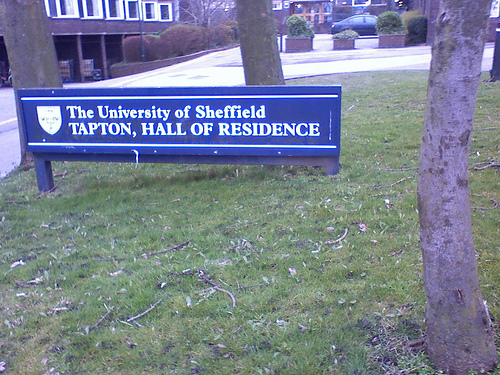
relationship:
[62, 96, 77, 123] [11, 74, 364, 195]
letter t on sign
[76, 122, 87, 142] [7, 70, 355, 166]
letter a on sign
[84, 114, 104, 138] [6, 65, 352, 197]
letter p on sign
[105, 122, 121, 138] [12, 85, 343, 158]
letter o on sign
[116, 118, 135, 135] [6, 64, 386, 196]
letter n on sign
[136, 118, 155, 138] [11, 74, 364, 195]
letter h on sign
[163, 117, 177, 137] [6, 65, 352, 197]
letter l on sign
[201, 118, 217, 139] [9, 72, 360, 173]
letter f on sign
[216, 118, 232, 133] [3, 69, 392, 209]
letter r on sign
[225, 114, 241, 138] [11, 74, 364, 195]
letter e on sign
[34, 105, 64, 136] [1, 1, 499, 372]
logo of university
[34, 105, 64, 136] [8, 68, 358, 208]
logo on sign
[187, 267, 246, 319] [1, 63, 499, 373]
stick on lawn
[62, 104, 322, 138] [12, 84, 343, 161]
text on sign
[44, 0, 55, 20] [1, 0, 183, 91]
window on building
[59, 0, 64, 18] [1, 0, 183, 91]
window on building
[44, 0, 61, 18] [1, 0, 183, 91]
window on building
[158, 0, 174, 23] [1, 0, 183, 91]
window on building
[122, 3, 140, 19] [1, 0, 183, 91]
window on building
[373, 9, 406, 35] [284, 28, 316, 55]
hedge coming out of pot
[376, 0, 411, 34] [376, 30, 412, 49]
hedge coming out of pot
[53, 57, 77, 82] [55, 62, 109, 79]
object behind fence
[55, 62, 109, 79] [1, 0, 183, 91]
fence under building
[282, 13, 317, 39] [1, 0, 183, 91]
bush outside building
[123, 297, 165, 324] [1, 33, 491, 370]
branch on ground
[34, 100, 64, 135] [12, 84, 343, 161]
logo on sign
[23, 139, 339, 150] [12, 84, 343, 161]
stripe on sign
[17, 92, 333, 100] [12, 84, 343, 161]
stripe on sign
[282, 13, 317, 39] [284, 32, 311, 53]
bush in planter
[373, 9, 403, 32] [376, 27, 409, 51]
bush in planter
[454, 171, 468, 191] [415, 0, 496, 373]
mark on tree trunk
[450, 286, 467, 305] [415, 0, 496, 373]
mark on tree trunk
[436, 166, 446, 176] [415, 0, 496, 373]
mark on tree trunk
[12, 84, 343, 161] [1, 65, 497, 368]
sign on grass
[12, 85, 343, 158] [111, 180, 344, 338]
sign in grass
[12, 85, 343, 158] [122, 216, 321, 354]
sign in grass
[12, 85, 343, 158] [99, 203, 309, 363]
sign in grass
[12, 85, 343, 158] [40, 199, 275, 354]
sign in grass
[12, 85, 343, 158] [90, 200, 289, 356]
sign in grass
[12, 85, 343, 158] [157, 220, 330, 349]
sign in grass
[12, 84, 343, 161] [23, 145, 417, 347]
sign in grass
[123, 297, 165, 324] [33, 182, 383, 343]
branch on grass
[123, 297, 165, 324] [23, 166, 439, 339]
branch on grass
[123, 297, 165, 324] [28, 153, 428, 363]
branch on grass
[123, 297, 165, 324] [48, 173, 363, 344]
branch on grass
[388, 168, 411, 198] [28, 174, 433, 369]
branch on grass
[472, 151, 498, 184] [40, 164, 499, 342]
branch on grass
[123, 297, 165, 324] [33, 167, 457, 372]
branch on grass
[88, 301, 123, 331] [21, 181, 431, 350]
branch on grass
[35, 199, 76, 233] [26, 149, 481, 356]
branch on grass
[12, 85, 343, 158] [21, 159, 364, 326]
sign in grass